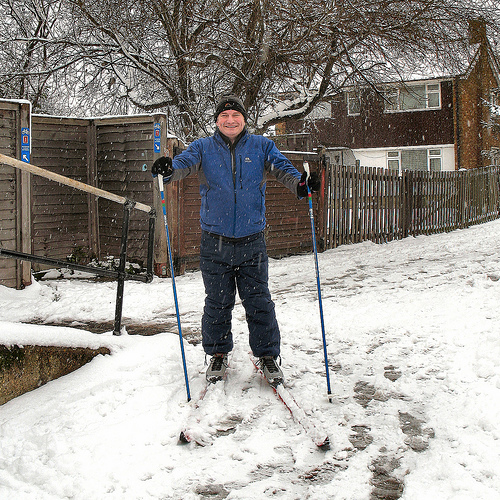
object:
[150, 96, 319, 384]
man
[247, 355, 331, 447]
skis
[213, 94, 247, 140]
head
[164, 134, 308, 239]
jacket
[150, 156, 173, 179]
glove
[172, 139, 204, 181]
arm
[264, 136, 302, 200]
arm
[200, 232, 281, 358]
snow pants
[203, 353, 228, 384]
shoes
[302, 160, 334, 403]
pole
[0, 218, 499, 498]
snow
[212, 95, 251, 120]
cap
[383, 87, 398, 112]
window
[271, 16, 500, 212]
house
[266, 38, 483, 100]
roof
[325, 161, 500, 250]
fence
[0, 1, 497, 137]
tree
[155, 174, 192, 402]
pole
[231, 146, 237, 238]
zipper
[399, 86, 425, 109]
pane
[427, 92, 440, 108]
pane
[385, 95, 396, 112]
pane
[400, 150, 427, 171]
pane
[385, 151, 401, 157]
window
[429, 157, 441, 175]
pane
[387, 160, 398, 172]
pane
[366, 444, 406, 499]
footprints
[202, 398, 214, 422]
snow